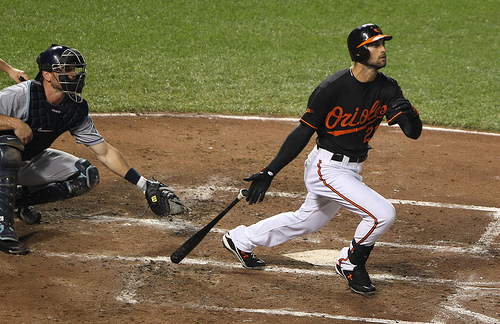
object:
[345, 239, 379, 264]
protection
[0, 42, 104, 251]
gear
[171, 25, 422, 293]
box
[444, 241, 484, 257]
chalk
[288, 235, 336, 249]
dirt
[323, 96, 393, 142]
name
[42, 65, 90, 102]
face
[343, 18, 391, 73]
head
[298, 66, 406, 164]
shirt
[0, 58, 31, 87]
hand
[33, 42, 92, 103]
head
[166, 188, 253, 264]
bat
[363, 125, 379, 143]
number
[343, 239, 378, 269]
pad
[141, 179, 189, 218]
glove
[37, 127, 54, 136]
logo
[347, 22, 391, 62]
hat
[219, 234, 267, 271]
cleat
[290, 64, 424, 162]
jersey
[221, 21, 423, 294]
player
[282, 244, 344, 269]
home plate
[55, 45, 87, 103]
mask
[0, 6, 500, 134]
grass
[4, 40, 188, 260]
catcher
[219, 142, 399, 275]
pants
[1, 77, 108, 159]
shirt